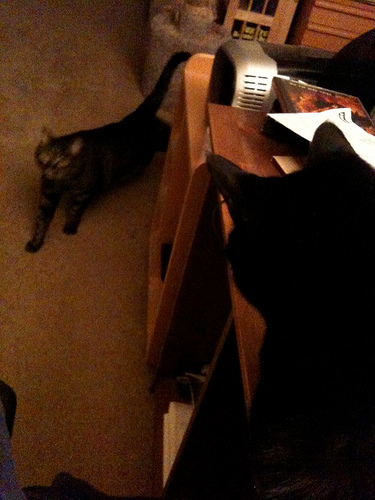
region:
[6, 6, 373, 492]
Two cats in a house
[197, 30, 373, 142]
Ink jet printer on top of a stand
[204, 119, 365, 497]
Black cat looking downward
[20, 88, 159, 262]
Grey and black cat walking on the floor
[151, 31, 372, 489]
Brown wooden office furniture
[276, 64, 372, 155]
DVD cover on top of a desk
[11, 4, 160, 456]
Carpet is light brown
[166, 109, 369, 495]
Black cat perched on top of a wooden desk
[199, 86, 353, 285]
Cats ears are raised upward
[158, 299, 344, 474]
documents inside of a desk shelf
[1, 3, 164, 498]
the floor has a tan carpet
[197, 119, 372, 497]
the black cat is sitting on the desk, looking at the tabby cat in the floor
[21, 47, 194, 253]
the tabby cat is stretching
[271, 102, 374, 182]
a letter is on the desk next to the cat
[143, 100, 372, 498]
the desk has compartments underneith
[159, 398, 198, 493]
a stack of papers is in the compartment beneath the desk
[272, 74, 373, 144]
a CD is beneath the letter on the desk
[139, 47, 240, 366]
a smaller table sits next to the big desk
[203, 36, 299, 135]
a silver and black heater sits on the smaller table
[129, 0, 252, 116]
a hearth is behind the cat on the ground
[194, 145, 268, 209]
large oval ear of cat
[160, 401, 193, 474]
white paper in cabinet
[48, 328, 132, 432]
dark gold carpet on floor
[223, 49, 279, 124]
white equipment on table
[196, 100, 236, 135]
edge of computer table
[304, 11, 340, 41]
large lines on tan cabinet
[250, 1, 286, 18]
glass in wood cabinet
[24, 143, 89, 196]
brown and tan cat's face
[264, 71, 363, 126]
multi colored CD on table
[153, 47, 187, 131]
cat's tail on floor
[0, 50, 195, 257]
cat on floor looking up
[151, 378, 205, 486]
stack of paper on shelf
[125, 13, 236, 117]
scratching post for a cat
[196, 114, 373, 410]
cat on desk, looking down at floor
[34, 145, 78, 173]
cat eyes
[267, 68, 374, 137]
cd on desk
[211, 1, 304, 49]
side of wooden piece of furniture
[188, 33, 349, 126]
part of a computer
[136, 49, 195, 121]
cat tail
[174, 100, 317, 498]
wooden desk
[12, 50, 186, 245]
a curious cat looking up at the camera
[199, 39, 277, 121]
a grey fan or speaker on top of a table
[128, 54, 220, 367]
a small brown wooden cart or table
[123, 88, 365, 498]
a wooden table or storage unit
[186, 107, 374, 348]
the head of a black cat looking down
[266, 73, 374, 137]
a music CD case on top of the table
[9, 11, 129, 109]
beige carpeting in the room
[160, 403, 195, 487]
some white papers on the bottom of the wooden unit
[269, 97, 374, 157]
a white envelope on the table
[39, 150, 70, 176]
the face of the cat on the floor